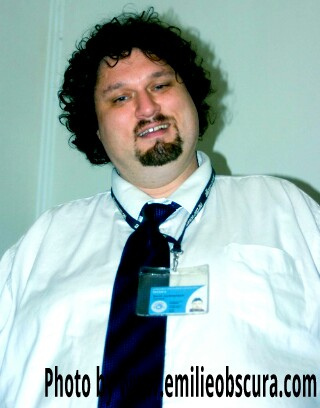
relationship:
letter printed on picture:
[301, 373, 309, 397] [1, 1, 309, 407]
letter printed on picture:
[283, 372, 292, 397] [1, 1, 309, 407]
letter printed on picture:
[268, 372, 278, 397] [1, 1, 309, 407]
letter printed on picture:
[261, 374, 268, 397] [1, 1, 309, 407]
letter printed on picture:
[250, 373, 261, 397] [1, 1, 309, 407]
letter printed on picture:
[242, 373, 251, 396] [1, 1, 309, 407]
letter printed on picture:
[234, 373, 243, 398] [1, 1, 309, 407]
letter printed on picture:
[224, 364, 234, 397] [1, 1, 309, 407]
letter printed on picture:
[214, 372, 225, 397] [1, 1, 309, 407]